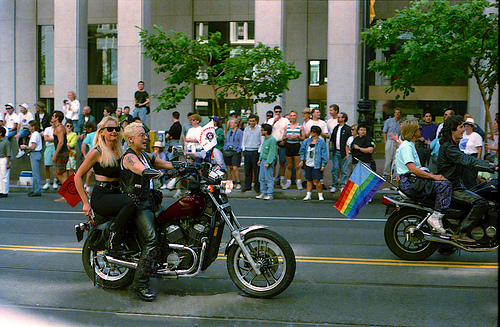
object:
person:
[119, 122, 206, 300]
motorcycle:
[75, 148, 296, 297]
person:
[74, 115, 136, 252]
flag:
[332, 160, 386, 220]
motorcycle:
[383, 164, 499, 259]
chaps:
[131, 203, 166, 287]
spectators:
[0, 81, 500, 202]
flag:
[59, 173, 89, 207]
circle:
[67, 182, 81, 195]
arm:
[123, 153, 181, 176]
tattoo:
[126, 156, 136, 167]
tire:
[81, 231, 137, 291]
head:
[121, 122, 148, 151]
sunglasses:
[101, 126, 122, 131]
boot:
[132, 284, 157, 301]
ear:
[100, 129, 104, 136]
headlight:
[218, 181, 234, 194]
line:
[0, 242, 500, 270]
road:
[1, 193, 500, 326]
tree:
[135, 25, 301, 129]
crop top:
[93, 144, 121, 178]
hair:
[93, 115, 125, 168]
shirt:
[258, 134, 277, 165]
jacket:
[299, 137, 328, 168]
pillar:
[326, 1, 364, 131]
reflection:
[41, 26, 467, 140]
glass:
[38, 26, 466, 139]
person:
[297, 126, 330, 202]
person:
[14, 105, 35, 159]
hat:
[19, 103, 29, 111]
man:
[434, 114, 499, 245]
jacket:
[429, 141, 495, 192]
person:
[282, 109, 306, 191]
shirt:
[287, 122, 303, 144]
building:
[1, 1, 500, 160]